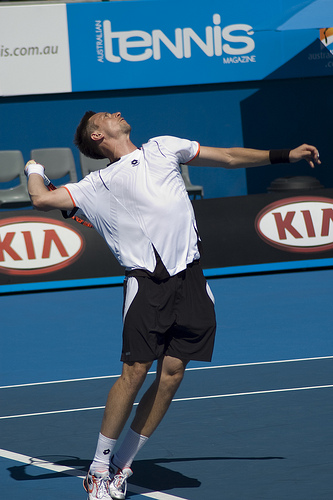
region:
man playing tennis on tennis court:
[56, 97, 232, 389]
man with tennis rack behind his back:
[16, 141, 135, 258]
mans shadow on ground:
[11, 427, 238, 493]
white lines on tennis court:
[4, 362, 206, 498]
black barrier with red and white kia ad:
[8, 204, 329, 278]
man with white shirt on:
[40, 134, 206, 287]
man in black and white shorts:
[110, 273, 227, 364]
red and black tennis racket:
[24, 151, 97, 229]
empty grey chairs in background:
[3, 135, 208, 213]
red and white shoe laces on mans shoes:
[82, 450, 140, 495]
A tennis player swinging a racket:
[20, 99, 324, 497]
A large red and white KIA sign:
[246, 190, 332, 268]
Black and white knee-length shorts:
[111, 256, 217, 389]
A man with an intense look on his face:
[68, 104, 150, 168]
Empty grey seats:
[0, 132, 219, 201]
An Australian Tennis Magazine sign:
[86, 8, 266, 73]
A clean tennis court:
[0, 365, 331, 498]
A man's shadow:
[6, 443, 296, 494]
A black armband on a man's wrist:
[245, 134, 325, 174]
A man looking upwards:
[64, 108, 171, 169]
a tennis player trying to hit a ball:
[14, 96, 328, 498]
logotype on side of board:
[255, 194, 332, 259]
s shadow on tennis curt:
[2, 439, 300, 497]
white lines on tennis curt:
[4, 352, 331, 495]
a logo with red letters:
[255, 191, 331, 252]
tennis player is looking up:
[19, 94, 327, 499]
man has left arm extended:
[5, 91, 331, 251]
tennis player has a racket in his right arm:
[9, 89, 325, 275]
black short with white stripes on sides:
[110, 257, 220, 373]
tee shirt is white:
[42, 129, 220, 288]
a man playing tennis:
[16, 80, 308, 383]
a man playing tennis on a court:
[21, 52, 286, 491]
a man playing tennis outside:
[23, 90, 278, 438]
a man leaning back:
[38, 53, 276, 310]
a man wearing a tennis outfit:
[52, 89, 233, 339]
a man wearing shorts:
[38, 90, 238, 354]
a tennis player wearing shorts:
[23, 97, 278, 378]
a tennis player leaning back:
[2, 62, 286, 277]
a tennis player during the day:
[1, 81, 275, 299]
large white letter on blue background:
[222, 22, 256, 58]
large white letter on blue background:
[211, 11, 222, 59]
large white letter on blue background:
[181, 23, 213, 61]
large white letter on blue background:
[151, 26, 184, 63]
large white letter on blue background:
[117, 28, 150, 61]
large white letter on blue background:
[102, 19, 120, 63]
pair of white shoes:
[82, 452, 137, 499]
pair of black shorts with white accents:
[116, 257, 219, 371]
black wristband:
[266, 145, 297, 166]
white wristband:
[24, 162, 46, 180]